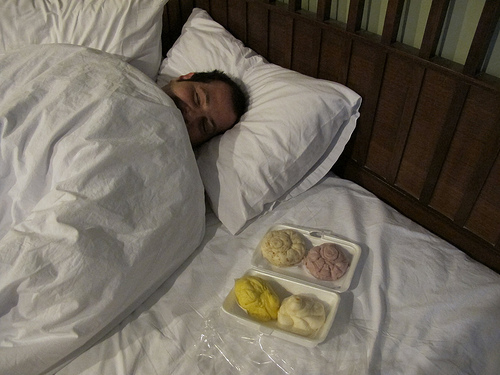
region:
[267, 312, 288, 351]
edge of a line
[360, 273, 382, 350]
part of a sheet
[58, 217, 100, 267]
part of a pillow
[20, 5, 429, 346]
this is a bedroom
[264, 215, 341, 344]
these are pastries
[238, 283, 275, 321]
this pastry is yellow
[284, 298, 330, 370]
this pastry is white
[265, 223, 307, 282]
this pastry is tan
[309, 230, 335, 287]
this pastry is light brown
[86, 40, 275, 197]
the man is in bed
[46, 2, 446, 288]
this is a bed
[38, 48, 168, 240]
this is a comforter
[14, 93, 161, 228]
the comforter is white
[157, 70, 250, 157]
A mans head on a pillow.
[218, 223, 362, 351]
A Styrofoam container with food.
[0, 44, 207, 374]
An all white comforter.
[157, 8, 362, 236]
A pillow with a man's head on it.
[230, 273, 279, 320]
An all yellow pastry.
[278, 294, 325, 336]
A white spiral shaped pastry.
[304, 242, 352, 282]
A pink colored pastry.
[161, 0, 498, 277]
A dark hardwood headboard.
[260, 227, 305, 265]
A green colored pastry.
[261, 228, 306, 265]
A green spiraled pastry.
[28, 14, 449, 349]
man laying in bed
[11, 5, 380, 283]
two white pillows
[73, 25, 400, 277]
a man under covers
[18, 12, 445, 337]
a man laying in bed on a pillow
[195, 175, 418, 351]
pastries in a styrofoam container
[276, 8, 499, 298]
a dark wooden head board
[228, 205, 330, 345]
Food in a white tray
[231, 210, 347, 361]
Food on a bed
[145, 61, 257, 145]
Man's head on a pillow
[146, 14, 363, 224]
Pillow on a bed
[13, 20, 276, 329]
Man under a white blanket